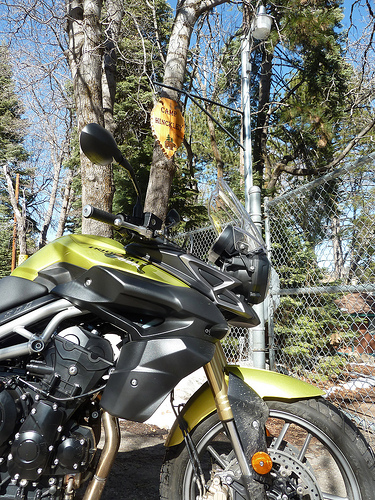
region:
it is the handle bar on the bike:
[81, 198, 114, 228]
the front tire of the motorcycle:
[151, 390, 373, 499]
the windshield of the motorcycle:
[210, 181, 251, 230]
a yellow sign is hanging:
[148, 93, 186, 155]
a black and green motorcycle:
[1, 234, 325, 497]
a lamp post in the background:
[233, 1, 272, 48]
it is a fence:
[260, 195, 369, 375]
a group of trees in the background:
[38, 9, 263, 224]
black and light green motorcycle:
[5, 234, 280, 495]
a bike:
[19, 234, 341, 497]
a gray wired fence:
[168, 179, 329, 402]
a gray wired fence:
[208, 137, 360, 347]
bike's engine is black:
[13, 285, 139, 497]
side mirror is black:
[59, 115, 165, 211]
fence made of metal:
[220, 180, 325, 388]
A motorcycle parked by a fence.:
[13, 31, 356, 498]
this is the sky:
[226, 16, 229, 20]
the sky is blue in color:
[354, 10, 360, 16]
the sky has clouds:
[14, 29, 54, 68]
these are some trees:
[61, 15, 372, 281]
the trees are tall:
[136, 18, 235, 56]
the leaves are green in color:
[293, 8, 317, 31]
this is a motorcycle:
[8, 115, 344, 498]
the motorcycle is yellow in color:
[60, 236, 78, 254]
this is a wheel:
[163, 374, 374, 496]